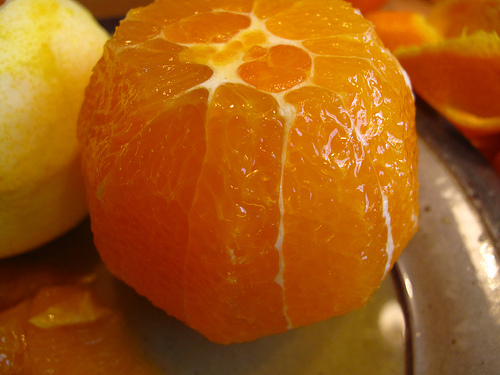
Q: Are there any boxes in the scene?
A: No, there are no boxes.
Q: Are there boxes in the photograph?
A: No, there are no boxes.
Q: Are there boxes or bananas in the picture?
A: No, there are no boxes or bananas.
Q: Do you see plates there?
A: Yes, there is a plate.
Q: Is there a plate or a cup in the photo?
A: Yes, there is a plate.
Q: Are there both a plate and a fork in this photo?
A: No, there is a plate but no forks.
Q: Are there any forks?
A: No, there are no forks.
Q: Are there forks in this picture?
A: No, there are no forks.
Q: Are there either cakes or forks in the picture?
A: No, there are no forks or cakes.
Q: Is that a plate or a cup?
A: That is a plate.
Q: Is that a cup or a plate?
A: That is a plate.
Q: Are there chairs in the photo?
A: No, there are no chairs.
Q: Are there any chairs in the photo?
A: No, there are no chairs.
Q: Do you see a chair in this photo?
A: No, there are no chairs.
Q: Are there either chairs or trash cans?
A: No, there are no chairs or trash cans.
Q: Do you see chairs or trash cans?
A: No, there are no chairs or trash cans.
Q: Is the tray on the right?
A: Yes, the tray is on the right of the image.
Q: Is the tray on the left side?
A: No, the tray is on the right of the image.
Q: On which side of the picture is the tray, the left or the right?
A: The tray is on the right of the image.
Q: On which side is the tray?
A: The tray is on the right of the image.